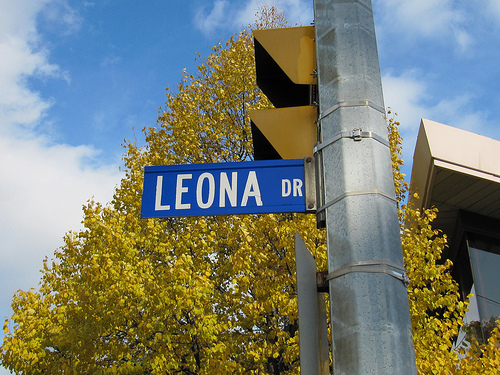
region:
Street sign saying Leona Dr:
[146, 166, 303, 213]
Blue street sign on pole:
[136, 162, 306, 213]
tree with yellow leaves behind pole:
[13, 212, 301, 368]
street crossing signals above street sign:
[244, 28, 322, 153]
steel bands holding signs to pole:
[321, 102, 411, 294]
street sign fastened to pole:
[288, 232, 417, 372]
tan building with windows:
[424, 116, 497, 323]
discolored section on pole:
[320, 20, 375, 92]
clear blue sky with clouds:
[3, 11, 115, 186]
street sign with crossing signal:
[132, 28, 434, 329]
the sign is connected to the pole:
[122, 150, 312, 232]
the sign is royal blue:
[112, 127, 315, 231]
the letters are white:
[116, 156, 307, 222]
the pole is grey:
[308, 11, 420, 370]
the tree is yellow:
[52, 27, 429, 354]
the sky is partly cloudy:
[28, 5, 230, 243]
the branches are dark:
[227, 287, 292, 369]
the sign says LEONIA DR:
[107, 156, 308, 209]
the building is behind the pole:
[386, 107, 496, 366]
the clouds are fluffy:
[13, 116, 119, 220]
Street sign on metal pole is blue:
[141, 161, 306, 219]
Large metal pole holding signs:
[313, 1, 413, 373]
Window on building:
[465, 235, 498, 304]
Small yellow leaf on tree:
[463, 292, 475, 298]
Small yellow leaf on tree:
[432, 310, 437, 316]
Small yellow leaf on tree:
[457, 319, 464, 326]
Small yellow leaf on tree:
[0, 314, 10, 324]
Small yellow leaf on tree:
[410, 189, 421, 199]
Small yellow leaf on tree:
[431, 203, 438, 213]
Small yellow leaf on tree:
[442, 241, 450, 247]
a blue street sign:
[137, 155, 308, 222]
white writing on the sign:
[148, 167, 264, 217]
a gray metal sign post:
[307, 0, 417, 370]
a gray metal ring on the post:
[312, 186, 402, 221]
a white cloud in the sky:
[0, 0, 147, 332]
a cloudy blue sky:
[1, 0, 498, 371]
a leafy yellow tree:
[0, 1, 498, 373]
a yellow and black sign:
[248, 22, 328, 108]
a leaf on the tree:
[409, 187, 424, 202]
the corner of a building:
[396, 108, 498, 243]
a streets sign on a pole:
[42, 95, 439, 326]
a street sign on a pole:
[94, 92, 419, 292]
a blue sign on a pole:
[83, 52, 470, 331]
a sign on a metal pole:
[75, 92, 499, 355]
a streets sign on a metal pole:
[101, 147, 473, 349]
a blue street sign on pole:
[110, 98, 496, 309]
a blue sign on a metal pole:
[108, 95, 498, 305]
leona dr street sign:
[94, 67, 496, 356]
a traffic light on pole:
[169, 2, 442, 228]